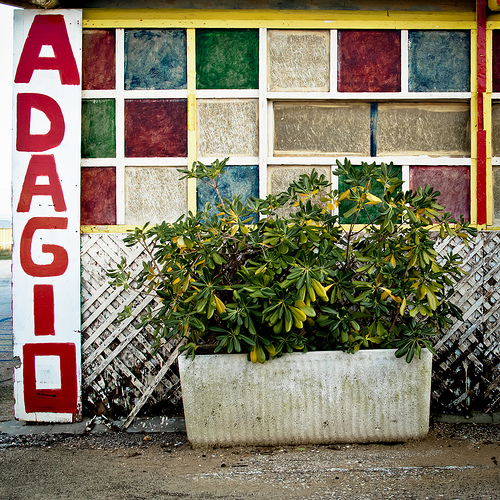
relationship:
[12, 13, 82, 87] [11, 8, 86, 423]
letter on front of sign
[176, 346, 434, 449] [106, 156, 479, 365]
pot with plant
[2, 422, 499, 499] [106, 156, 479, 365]
ground in front of plant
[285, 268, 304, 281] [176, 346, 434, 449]
leaf growing in pot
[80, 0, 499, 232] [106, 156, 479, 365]
wall above plant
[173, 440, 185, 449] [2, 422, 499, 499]
rock laying on ground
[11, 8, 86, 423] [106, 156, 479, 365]
sign next to plant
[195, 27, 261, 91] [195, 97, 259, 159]
tile above tile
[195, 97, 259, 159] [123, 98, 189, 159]
tile next to tile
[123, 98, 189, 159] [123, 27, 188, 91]
tile next to tile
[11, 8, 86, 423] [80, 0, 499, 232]
sign leaning against wall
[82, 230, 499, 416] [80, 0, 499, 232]
trellis on front of wall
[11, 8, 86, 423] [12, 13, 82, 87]
sign has letter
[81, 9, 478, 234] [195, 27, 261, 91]
trim around tile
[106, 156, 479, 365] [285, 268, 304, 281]
plant has leaf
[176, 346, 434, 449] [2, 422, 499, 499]
pot sitting on ground